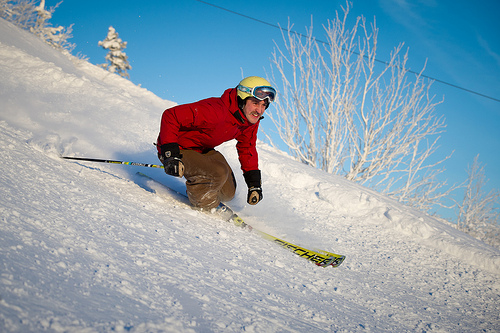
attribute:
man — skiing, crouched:
[156, 76, 278, 214]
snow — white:
[1, 17, 499, 329]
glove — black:
[244, 172, 268, 205]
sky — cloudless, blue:
[1, 1, 498, 232]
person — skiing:
[157, 76, 278, 217]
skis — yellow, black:
[135, 169, 347, 269]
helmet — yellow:
[236, 75, 276, 107]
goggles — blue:
[252, 85, 277, 103]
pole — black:
[59, 155, 185, 176]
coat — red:
[156, 86, 265, 170]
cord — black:
[196, 1, 495, 103]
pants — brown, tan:
[154, 142, 237, 207]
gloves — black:
[159, 142, 186, 177]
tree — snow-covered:
[103, 27, 131, 74]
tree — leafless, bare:
[263, 12, 440, 176]